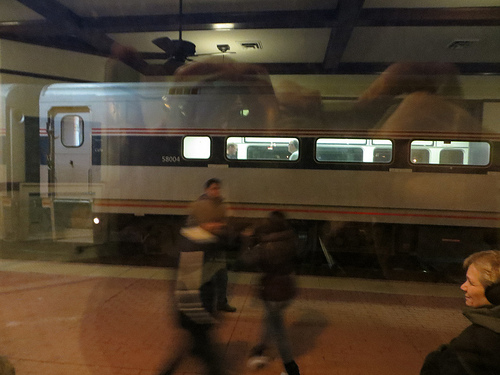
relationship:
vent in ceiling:
[445, 27, 488, 71] [102, 19, 363, 72]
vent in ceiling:
[233, 37, 263, 51] [1, 0, 499, 75]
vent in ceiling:
[443, 35, 479, 54] [1, 0, 499, 75]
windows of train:
[170, 115, 499, 187] [30, 68, 497, 268]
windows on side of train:
[166, 130, 484, 170] [30, 68, 497, 268]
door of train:
[39, 104, 105, 252] [98, 78, 451, 210]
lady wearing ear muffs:
[429, 245, 474, 368] [480, 276, 497, 305]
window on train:
[409, 137, 491, 169] [38, 77, 494, 282]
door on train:
[39, 104, 111, 193] [29, 71, 498, 230]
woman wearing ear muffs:
[418, 248, 497, 373] [480, 276, 497, 305]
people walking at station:
[164, 175, 309, 373] [4, 4, 497, 364]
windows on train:
[176, 131, 497, 178] [38, 77, 494, 282]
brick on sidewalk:
[94, 265, 202, 316] [0, 245, 495, 372]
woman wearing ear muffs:
[418, 248, 497, 373] [485, 280, 498, 306]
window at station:
[6, 5, 493, 372] [4, 4, 497, 364]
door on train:
[39, 104, 105, 252] [30, 68, 497, 268]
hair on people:
[462, 246, 497, 297] [233, 199, 308, 373]